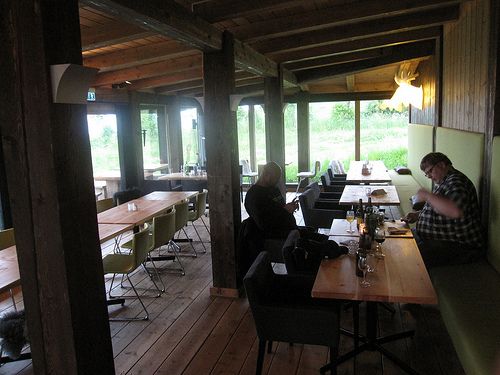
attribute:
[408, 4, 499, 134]
wall — wood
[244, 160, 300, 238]
man — bald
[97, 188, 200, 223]
table — wood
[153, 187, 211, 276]
chairs — empty, plastic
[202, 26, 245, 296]
posts — wood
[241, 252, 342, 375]
chair — cloth backed, empty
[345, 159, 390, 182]
table — wooden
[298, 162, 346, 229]
chairs — black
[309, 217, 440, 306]
table — brown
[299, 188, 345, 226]
chair — empty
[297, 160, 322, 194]
chair — empty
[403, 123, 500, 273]
headboards — green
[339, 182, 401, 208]
table — wood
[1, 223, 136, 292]
table — wood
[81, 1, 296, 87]
beams — wood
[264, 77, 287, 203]
posts — wooden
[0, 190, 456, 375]
patio — wood, brown, wide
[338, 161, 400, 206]
tables — wood